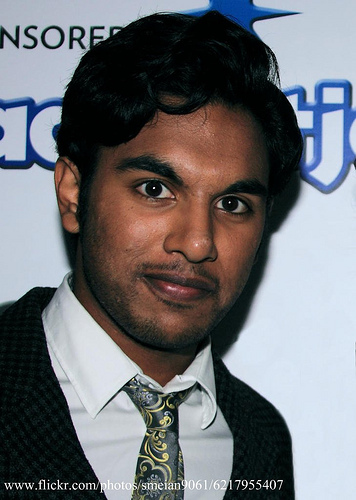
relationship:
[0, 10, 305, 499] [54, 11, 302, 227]
man has hair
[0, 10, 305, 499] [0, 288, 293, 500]
man wearing suit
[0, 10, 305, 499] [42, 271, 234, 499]
man wearing shirt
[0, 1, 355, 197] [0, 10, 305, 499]
advertisement behind man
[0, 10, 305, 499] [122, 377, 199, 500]
man wearing tie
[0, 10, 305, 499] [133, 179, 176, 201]
man has eye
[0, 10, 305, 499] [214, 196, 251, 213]
man has eye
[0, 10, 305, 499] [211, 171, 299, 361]
man casts shadow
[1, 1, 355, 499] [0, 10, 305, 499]
billboard behind man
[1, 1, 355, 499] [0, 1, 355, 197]
billboard has advertisement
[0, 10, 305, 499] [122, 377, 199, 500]
man wears tie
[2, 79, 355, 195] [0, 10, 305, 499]
word behind man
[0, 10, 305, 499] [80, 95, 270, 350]
man has face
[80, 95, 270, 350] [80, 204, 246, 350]
face has whiskers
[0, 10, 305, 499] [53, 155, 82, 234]
man has ear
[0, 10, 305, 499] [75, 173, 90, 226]
man has sideburn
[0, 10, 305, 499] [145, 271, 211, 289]
man has lip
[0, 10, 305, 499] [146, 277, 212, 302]
man has lip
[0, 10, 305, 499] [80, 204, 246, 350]
man has whiskers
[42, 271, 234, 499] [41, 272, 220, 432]
shirt has collar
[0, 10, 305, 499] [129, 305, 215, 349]
man has chin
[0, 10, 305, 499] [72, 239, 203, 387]
man has neck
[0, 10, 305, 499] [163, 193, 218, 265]
man has nose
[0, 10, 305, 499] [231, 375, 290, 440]
man has shoulder